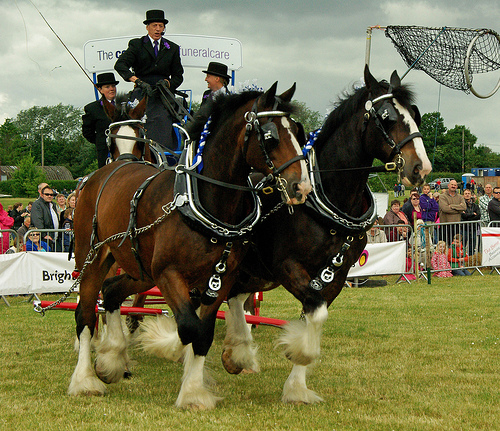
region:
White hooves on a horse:
[51, 309, 160, 429]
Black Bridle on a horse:
[166, 121, 281, 257]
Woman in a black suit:
[77, 66, 157, 161]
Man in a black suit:
[112, 8, 202, 135]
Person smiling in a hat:
[191, 57, 264, 126]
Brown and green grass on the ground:
[338, 286, 483, 411]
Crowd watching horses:
[371, 168, 498, 281]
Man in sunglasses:
[23, 186, 73, 236]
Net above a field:
[361, 16, 498, 98]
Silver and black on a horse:
[188, 219, 241, 306]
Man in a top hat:
[118, 7, 190, 132]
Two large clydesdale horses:
[52, 66, 441, 409]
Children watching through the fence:
[423, 227, 479, 291]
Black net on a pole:
[370, 17, 499, 95]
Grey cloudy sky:
[4, 2, 497, 132]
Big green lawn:
[3, 180, 498, 425]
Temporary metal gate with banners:
[1, 211, 497, 308]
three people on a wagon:
[71, 12, 271, 165]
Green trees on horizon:
[4, 94, 496, 185]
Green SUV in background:
[423, 167, 461, 196]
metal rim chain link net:
[380, 20, 497, 100]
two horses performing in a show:
[65, 63, 432, 414]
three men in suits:
[82, 7, 235, 148]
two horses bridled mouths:
[175, 63, 432, 240]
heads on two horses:
[188, 65, 435, 223]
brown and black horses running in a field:
[68, 10, 432, 412]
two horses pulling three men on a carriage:
[67, 8, 498, 428]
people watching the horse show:
[2, 180, 71, 245]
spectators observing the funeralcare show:
[387, 179, 497, 279]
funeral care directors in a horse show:
[62, 7, 437, 412]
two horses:
[66, 64, 405, 424]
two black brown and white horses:
[84, 62, 463, 428]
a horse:
[59, 87, 325, 400]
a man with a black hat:
[119, 9, 199, 124]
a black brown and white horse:
[59, 85, 330, 430]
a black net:
[357, 19, 499, 119]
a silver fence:
[10, 218, 497, 275]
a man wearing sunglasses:
[26, 184, 86, 272]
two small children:
[419, 220, 493, 310]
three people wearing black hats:
[65, 11, 255, 133]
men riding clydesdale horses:
[53, 7, 457, 412]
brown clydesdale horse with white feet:
[40, 85, 313, 411]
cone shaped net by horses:
[356, 14, 499, 110]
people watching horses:
[9, 181, 61, 308]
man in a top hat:
[108, 8, 191, 108]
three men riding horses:
[61, 7, 246, 129]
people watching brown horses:
[383, 183, 492, 260]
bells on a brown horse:
[181, 234, 245, 319]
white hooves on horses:
[70, 306, 230, 411]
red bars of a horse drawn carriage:
[33, 253, 295, 355]